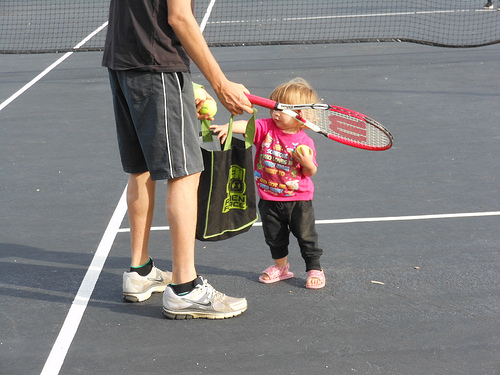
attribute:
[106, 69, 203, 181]
shorts — black 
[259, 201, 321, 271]
pants — black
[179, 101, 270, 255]
bag — black , fabric 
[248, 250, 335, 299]
pink shoes — pink 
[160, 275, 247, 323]
shoe — white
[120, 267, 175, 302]
shoe — white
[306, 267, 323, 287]
shoes — pink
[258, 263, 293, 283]
shoes — little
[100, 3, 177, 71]
black shirt — black 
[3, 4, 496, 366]
picture — taken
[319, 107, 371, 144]
w — pink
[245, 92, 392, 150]
racket — red and white, pink, white and black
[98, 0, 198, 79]
shirt — black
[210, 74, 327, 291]
child — small 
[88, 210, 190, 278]
lines — white 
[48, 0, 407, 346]
picture — taken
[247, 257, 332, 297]
chappel — pink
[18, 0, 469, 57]
net — black 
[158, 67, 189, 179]
stripes — white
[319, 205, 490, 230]
line — white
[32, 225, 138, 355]
line — white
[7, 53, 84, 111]
line — white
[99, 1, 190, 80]
shirt — black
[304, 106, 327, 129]
strings — white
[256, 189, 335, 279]
pants — black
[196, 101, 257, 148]
handles — green 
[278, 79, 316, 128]
hair — blond 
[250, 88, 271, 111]
handle — red 